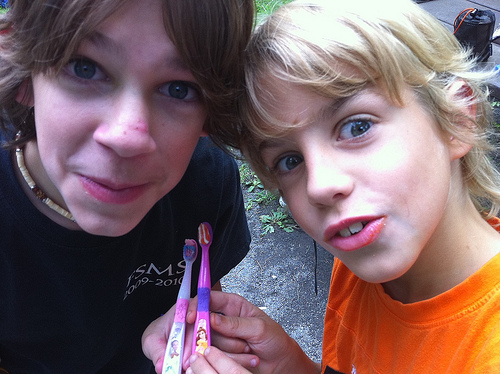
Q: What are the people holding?
A: Toothbrushes.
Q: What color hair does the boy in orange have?
A: Blonde.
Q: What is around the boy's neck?
A: Necklace.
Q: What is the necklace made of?
A: Beads.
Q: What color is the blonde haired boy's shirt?
A: Orange.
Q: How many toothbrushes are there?
A: Two.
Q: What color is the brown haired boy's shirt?
A: Black.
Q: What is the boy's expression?
A: Smiling.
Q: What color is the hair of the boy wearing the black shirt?
A: Brown.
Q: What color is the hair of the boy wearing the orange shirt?
A: Blonde.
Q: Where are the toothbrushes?
A: Boys' hands.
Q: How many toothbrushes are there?
A: 2.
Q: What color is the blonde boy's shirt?
A: Orange.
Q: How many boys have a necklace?
A: 1.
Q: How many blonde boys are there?
A: 1.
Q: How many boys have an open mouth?
A: 1.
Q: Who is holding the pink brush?
A: Blonde boy.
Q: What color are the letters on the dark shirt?
A: White.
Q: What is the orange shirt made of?
A: Cotton.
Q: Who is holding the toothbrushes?
A: Two boys.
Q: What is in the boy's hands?
A: Toothbrushes.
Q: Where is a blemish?
A: On the left boy's nose.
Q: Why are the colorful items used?
A: To brush teeth.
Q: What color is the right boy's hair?
A: Blonde.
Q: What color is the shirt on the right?
A: Orange.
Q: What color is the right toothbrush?
A: Pink.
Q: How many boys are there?
A: 2.